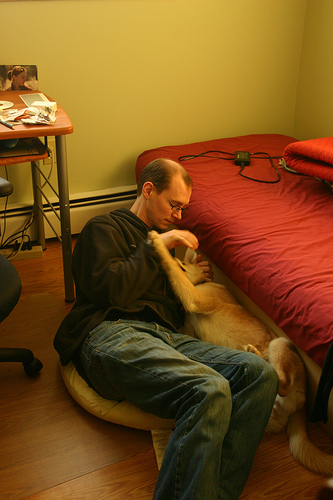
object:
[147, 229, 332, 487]
dog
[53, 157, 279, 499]
man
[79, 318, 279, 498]
jeans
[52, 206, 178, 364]
shirt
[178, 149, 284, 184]
charger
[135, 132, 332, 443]
bed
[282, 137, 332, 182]
blanket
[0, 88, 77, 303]
desk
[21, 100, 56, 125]
paper